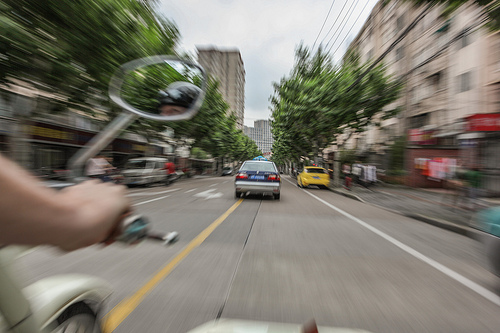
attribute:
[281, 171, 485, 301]
line — white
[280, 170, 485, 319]
line — white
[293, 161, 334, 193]
taxi — yellow, parked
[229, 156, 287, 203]
car — blue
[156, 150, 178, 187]
person — walking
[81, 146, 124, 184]
person — walking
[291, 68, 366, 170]
trees — green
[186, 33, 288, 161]
buildings — city, tall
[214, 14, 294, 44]
sky — grey, cloudy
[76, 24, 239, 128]
mirror — from a scooter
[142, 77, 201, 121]
reflection — sunglasses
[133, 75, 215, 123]
helmet — black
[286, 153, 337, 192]
car — yellow, parked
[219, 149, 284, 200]
car — blue, silver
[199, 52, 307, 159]
building — tall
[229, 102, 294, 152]
building — tall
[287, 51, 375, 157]
tree — leafy, green